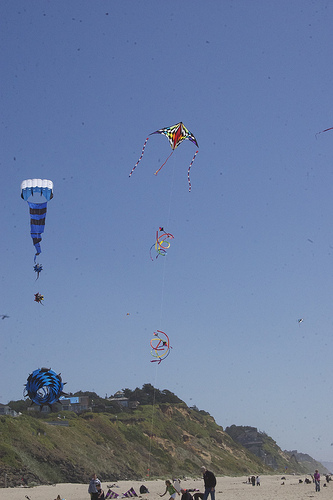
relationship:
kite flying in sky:
[127, 120, 200, 192] [3, 4, 332, 461]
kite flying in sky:
[147, 224, 176, 260] [3, 4, 332, 461]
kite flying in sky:
[148, 328, 172, 365] [3, 4, 332, 461]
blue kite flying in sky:
[15, 168, 55, 292] [3, 4, 332, 461]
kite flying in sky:
[20, 364, 69, 412] [3, 4, 332, 461]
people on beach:
[88, 466, 332, 499] [2, 471, 330, 498]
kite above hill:
[23, 366, 70, 412] [11, 415, 116, 473]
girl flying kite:
[158, 478, 181, 499] [125, 110, 200, 365]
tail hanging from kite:
[155, 146, 177, 174] [127, 120, 200, 192]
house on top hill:
[56, 393, 90, 412] [1, 381, 327, 479]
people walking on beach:
[255, 475, 260, 486] [2, 471, 330, 498]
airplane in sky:
[116, 101, 226, 195] [188, 28, 298, 101]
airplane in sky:
[296, 318, 309, 327] [1, 3, 328, 407]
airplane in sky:
[297, 318, 303, 323] [3, 4, 332, 461]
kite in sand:
[123, 487, 137, 496] [1, 480, 327, 499]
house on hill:
[2, 403, 22, 417] [1, 381, 327, 479]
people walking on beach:
[242, 474, 267, 488] [2, 471, 330, 498]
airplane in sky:
[19, 170, 51, 262] [3, 4, 332, 461]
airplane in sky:
[20, 178, 54, 264] [3, 4, 332, 461]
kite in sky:
[147, 224, 176, 260] [3, 4, 332, 461]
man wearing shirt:
[194, 462, 228, 495] [202, 471, 214, 492]